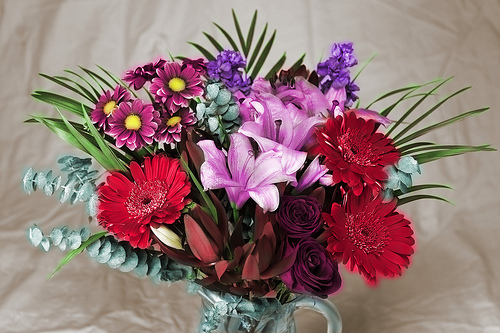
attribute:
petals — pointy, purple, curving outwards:
[159, 59, 199, 77]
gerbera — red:
[320, 113, 420, 290]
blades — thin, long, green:
[357, 74, 493, 212]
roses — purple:
[18, 0, 498, 331]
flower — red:
[93, 147, 197, 237]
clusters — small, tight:
[271, 187, 349, 294]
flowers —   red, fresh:
[23, 7, 496, 302]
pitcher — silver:
[185, 280, 340, 330]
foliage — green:
[186, 61, 244, 135]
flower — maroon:
[234, 199, 304, 300]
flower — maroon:
[160, 201, 242, 283]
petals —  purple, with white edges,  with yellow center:
[231, 144, 298, 198]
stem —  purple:
[327, 98, 337, 117]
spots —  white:
[125, 182, 168, 217]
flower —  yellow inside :
[147, 64, 202, 111]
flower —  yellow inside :
[159, 108, 193, 138]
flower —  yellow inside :
[113, 111, 153, 143]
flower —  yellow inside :
[93, 89, 126, 126]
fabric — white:
[0, 3, 495, 331]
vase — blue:
[190, 283, 351, 332]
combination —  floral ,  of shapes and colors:
[22, 10, 499, 330]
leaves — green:
[23, 64, 142, 181]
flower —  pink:
[189, 131, 311, 246]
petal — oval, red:
[129, 162, 144, 182]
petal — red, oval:
[105, 172, 129, 192]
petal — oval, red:
[169, 178, 184, 198]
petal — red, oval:
[143, 212, 151, 222]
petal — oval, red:
[107, 212, 132, 219]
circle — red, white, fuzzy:
[126, 178, 163, 211]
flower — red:
[89, 150, 199, 259]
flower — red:
[100, 93, 164, 154]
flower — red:
[145, 55, 207, 114]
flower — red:
[152, 106, 199, 149]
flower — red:
[121, 54, 178, 94]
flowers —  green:
[72, 70, 469, 302]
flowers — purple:
[125, 57, 355, 254]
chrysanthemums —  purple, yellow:
[91, 54, 209, 152]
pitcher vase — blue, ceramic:
[186, 281, 343, 331]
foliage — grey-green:
[12, 223, 214, 297]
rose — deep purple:
[280, 238, 341, 296]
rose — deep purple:
[275, 192, 325, 237]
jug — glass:
[192, 285, 340, 331]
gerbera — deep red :
[319, 182, 417, 283]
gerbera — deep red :
[314, 110, 400, 194]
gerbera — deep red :
[97, 152, 184, 251]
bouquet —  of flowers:
[18, 8, 497, 330]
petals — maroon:
[288, 241, 304, 281]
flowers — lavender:
[200, 72, 360, 212]